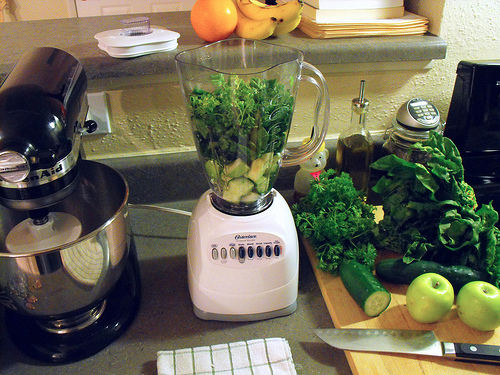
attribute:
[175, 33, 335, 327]
blender — full, white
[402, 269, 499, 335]
apples — green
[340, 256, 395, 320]
cucumber — cut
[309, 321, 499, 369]
knife — sharp, large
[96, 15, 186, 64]
lid — white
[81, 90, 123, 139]
outlet — white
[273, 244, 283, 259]
button — small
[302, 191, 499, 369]
board — wood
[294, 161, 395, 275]
leaves — green